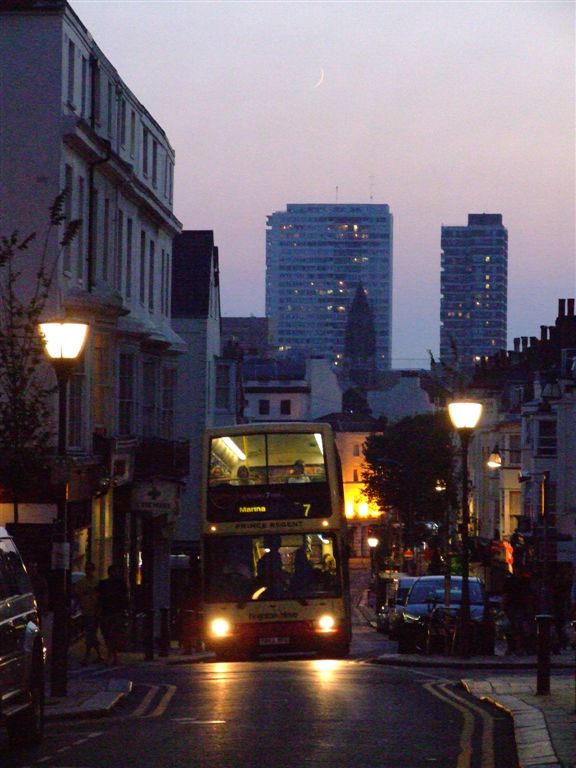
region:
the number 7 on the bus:
[296, 497, 314, 525]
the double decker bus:
[206, 421, 341, 652]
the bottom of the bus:
[202, 537, 343, 665]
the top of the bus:
[202, 421, 337, 518]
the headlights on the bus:
[203, 607, 356, 649]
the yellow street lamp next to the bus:
[445, 400, 491, 663]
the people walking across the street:
[80, 551, 135, 665]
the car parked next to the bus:
[390, 585, 494, 647]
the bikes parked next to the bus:
[414, 601, 485, 656]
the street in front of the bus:
[130, 658, 469, 767]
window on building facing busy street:
[257, 396, 272, 415]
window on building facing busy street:
[509, 490, 518, 530]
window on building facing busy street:
[511, 438, 521, 462]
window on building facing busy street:
[536, 479, 556, 521]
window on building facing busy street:
[537, 416, 558, 458]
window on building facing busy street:
[351, 442, 360, 456]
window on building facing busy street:
[120, 351, 133, 438]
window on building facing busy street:
[137, 229, 146, 309]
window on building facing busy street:
[279, 398, 292, 414]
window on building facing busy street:
[70, 352, 155, 449]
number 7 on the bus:
[297, 497, 315, 519]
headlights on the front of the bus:
[206, 610, 336, 644]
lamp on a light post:
[436, 391, 487, 653]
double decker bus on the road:
[198, 425, 350, 656]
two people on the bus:
[220, 459, 310, 485]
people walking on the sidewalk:
[62, 557, 132, 670]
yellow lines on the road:
[441, 710, 500, 766]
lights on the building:
[344, 484, 381, 523]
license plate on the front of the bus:
[253, 629, 295, 649]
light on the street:
[305, 654, 353, 695]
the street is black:
[265, 708, 314, 749]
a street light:
[39, 321, 85, 358]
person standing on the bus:
[256, 534, 296, 589]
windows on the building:
[278, 256, 344, 330]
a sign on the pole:
[52, 544, 72, 571]